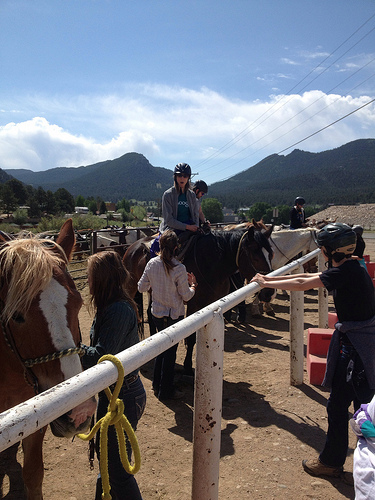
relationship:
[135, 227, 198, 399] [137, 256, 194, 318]
lady wearing shirt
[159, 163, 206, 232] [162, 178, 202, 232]
woman wearing cardigan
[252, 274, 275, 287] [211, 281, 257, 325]
hand holding rail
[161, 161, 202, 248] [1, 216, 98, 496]
person on horse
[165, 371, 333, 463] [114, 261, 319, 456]
shadows under railing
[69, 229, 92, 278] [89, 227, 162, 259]
gate on fence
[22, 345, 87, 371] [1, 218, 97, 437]
rope on face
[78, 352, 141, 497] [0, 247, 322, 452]
rope to bar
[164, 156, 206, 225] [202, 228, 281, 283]
woman on a horse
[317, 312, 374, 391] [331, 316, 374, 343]
sweatshirt tied around waist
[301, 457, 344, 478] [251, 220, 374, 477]
shoe on boy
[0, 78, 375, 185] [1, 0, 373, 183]
clouds in sky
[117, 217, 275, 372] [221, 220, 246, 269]
horse wearing harness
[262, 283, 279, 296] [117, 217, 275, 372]
nose belonging to horse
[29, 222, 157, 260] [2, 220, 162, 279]
herd standing in kennel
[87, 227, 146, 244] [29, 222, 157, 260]
horse standing in herd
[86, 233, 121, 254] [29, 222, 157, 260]
horse standing in herd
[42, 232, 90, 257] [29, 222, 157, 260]
horse standing in herd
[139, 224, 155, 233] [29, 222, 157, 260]
horse standing in herd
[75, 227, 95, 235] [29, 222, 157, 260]
horse standing in herd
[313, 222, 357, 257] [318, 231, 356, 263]
helmet worn on head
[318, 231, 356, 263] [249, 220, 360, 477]
head belonging to boy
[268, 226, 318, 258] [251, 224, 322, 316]
neck belonging to horse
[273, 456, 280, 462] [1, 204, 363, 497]
rock lying on ground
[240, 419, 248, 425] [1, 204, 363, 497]
rock lying on ground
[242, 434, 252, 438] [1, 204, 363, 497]
rock lying on ground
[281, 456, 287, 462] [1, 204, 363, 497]
rock lying on ground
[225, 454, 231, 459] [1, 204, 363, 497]
rock lying on ground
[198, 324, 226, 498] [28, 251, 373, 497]
pole standing on ground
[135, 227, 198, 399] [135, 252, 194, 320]
lady wearing shirt